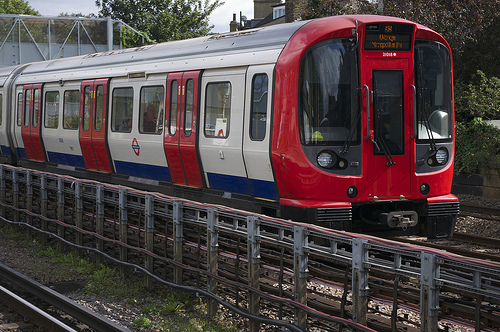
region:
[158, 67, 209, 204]
First red train door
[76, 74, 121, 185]
Second red train door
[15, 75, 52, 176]
Third red train door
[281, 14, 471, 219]
Front of the train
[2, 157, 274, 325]
Bottom of the train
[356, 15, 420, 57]
The trains led display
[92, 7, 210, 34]
Tree in the backgroun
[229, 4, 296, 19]
Building behind the train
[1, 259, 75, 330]
Part of another train track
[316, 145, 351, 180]
Headlight on the left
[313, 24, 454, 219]
The color of the train is a deep red color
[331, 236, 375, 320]
The fence is very deep silver in color and aged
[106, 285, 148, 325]
The color of the grass is very, very deep green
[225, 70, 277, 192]
The color of the train in the back is white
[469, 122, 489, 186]
The color the trees is very deep green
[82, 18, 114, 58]
The silver color of the fence is very appealing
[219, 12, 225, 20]
The color of the sky is very slightly cloudy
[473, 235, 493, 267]
The color of the train tracks is a deep brown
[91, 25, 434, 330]
This photo was taken in the country of United Kingdom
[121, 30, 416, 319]
The location of this photo is the city of London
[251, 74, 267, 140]
a window on a train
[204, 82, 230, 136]
a window on a train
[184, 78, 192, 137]
a window on a train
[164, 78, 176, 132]
a window on a train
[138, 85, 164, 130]
a window on a train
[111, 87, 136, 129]
a window on a train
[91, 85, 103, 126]
a window on a train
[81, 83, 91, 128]
a window on a train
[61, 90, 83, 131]
a window on a train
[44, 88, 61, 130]
a window on a train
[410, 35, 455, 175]
Left windshield of train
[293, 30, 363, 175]
Right windshield of train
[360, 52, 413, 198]
Front door of train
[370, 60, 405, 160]
Front door window of train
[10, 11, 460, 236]
Red and gray passenger train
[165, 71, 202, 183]
Passenger entrance/exit door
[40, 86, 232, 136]
Five passenger windows on right side of train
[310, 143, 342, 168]
Right headlight of train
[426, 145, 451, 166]
Left headlight of train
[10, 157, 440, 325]
Fence along side of train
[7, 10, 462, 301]
a train from the london tube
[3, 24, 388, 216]
a red, blue and grey train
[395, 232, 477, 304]
train tracks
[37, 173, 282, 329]
a barrier to the subway tracks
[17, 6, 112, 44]
a pedestrian bridge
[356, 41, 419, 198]
conductor's door for the train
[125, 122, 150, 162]
the london underground logo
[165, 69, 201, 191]
a sliding passenger door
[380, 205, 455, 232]
a tow hitch for another train car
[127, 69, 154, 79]
sign indicating the train's course